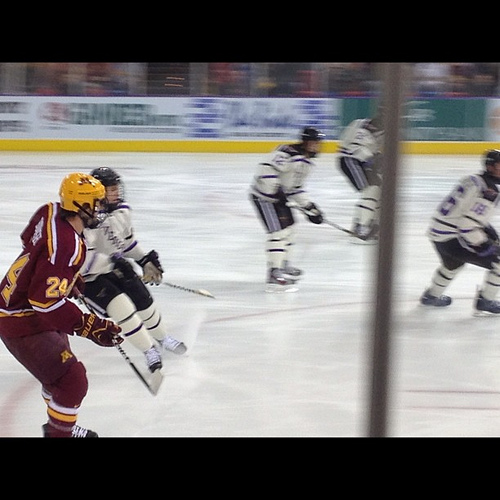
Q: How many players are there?
A: Five.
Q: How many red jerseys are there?
A: One.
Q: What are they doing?
A: Playing hockey.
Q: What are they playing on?
A: Ice.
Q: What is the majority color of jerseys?
A: White.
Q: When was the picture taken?
A: Hockey season.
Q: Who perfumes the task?
A: Hockey players.